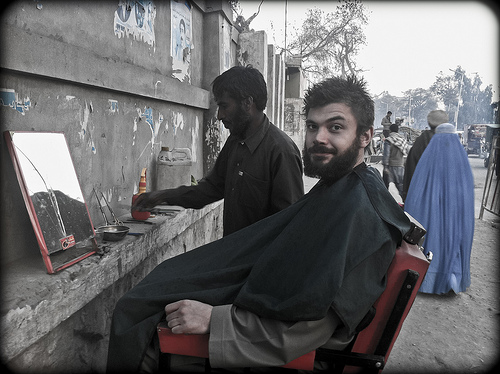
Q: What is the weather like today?
A: It is cloudy.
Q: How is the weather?
A: It is cloudy.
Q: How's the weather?
A: It is cloudy.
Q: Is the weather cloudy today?
A: Yes, it is cloudy.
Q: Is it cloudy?
A: Yes, it is cloudy.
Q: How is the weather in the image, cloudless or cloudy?
A: It is cloudy.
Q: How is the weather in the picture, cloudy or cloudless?
A: It is cloudy.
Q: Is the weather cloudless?
A: No, it is cloudy.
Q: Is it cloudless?
A: No, it is cloudy.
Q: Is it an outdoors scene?
A: Yes, it is outdoors.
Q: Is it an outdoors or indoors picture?
A: It is outdoors.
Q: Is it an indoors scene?
A: No, it is outdoors.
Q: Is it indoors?
A: No, it is outdoors.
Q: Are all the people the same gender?
A: No, they are both male and female.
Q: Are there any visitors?
A: No, there are no visitors.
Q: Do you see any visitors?
A: No, there are no visitors.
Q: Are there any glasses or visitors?
A: No, there are no visitors or glasses.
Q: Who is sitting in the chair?
A: The man is sitting in the chair.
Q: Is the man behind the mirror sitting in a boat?
A: No, the man is sitting in the chair.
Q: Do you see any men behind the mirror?
A: Yes, there is a man behind the mirror.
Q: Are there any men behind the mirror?
A: Yes, there is a man behind the mirror.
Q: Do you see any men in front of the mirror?
A: No, the man is behind the mirror.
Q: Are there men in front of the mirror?
A: No, the man is behind the mirror.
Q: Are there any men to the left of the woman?
A: Yes, there is a man to the left of the woman.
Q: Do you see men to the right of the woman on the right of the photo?
A: No, the man is to the left of the woman.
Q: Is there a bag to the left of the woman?
A: No, there is a man to the left of the woman.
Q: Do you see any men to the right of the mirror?
A: Yes, there is a man to the right of the mirror.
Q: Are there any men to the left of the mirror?
A: No, the man is to the right of the mirror.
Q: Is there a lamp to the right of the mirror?
A: No, there is a man to the right of the mirror.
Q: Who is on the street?
A: The man is on the street.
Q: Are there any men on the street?
A: Yes, there is a man on the street.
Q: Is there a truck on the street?
A: No, there is a man on the street.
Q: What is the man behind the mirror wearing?
A: The man is wearing a shirt.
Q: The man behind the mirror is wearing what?
A: The man is wearing a shirt.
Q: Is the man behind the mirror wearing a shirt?
A: Yes, the man is wearing a shirt.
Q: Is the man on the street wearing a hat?
A: No, the man is wearing a shirt.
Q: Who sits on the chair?
A: The man sits on the chair.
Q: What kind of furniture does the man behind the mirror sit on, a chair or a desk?
A: The man sits on a chair.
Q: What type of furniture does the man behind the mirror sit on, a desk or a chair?
A: The man sits on a chair.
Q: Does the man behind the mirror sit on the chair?
A: Yes, the man sits on the chair.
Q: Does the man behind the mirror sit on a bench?
A: No, the man sits on the chair.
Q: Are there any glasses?
A: No, there are no glasses.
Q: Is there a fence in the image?
A: No, there are no fences.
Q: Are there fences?
A: No, there are no fences.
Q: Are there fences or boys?
A: No, there are no fences or boys.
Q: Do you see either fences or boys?
A: No, there are no fences or boys.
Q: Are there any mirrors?
A: Yes, there is a mirror.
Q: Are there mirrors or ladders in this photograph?
A: Yes, there is a mirror.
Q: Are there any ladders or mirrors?
A: Yes, there is a mirror.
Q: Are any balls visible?
A: No, there are no balls.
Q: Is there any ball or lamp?
A: No, there are no balls or lamps.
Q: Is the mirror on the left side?
A: Yes, the mirror is on the left of the image.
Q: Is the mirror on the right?
A: No, the mirror is on the left of the image.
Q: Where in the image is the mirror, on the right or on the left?
A: The mirror is on the left of the image.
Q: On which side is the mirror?
A: The mirror is on the left of the image.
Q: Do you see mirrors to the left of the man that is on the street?
A: Yes, there is a mirror to the left of the man.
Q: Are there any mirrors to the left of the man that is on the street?
A: Yes, there is a mirror to the left of the man.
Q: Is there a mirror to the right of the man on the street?
A: No, the mirror is to the left of the man.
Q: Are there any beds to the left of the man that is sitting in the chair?
A: No, there is a mirror to the left of the man.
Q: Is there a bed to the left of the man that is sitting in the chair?
A: No, there is a mirror to the left of the man.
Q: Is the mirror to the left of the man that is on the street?
A: Yes, the mirror is to the left of the man.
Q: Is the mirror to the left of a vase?
A: No, the mirror is to the left of the man.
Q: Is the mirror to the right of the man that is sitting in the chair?
A: No, the mirror is to the left of the man.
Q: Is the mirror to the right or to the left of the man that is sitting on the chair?
A: The mirror is to the left of the man.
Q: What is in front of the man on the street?
A: The mirror is in front of the man.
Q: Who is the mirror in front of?
A: The mirror is in front of the man.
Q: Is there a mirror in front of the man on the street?
A: Yes, there is a mirror in front of the man.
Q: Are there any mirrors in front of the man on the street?
A: Yes, there is a mirror in front of the man.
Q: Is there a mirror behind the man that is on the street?
A: No, the mirror is in front of the man.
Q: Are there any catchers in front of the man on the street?
A: No, there is a mirror in front of the man.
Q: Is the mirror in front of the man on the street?
A: Yes, the mirror is in front of the man.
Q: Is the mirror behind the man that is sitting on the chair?
A: No, the mirror is in front of the man.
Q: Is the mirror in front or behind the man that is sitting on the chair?
A: The mirror is in front of the man.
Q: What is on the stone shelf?
A: The mirror is on the shelf.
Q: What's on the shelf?
A: The mirror is on the shelf.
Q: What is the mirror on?
A: The mirror is on the shelf.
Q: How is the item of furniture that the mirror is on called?
A: The piece of furniture is a shelf.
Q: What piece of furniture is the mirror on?
A: The mirror is on the shelf.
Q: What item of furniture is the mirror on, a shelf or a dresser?
A: The mirror is on a shelf.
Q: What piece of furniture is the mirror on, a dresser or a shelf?
A: The mirror is on a shelf.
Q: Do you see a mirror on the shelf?
A: Yes, there is a mirror on the shelf.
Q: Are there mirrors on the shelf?
A: Yes, there is a mirror on the shelf.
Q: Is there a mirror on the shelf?
A: Yes, there is a mirror on the shelf.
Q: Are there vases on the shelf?
A: No, there is a mirror on the shelf.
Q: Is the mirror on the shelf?
A: Yes, the mirror is on the shelf.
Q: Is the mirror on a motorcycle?
A: No, the mirror is on the shelf.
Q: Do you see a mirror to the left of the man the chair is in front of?
A: Yes, there is a mirror to the left of the man.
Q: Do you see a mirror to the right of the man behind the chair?
A: No, the mirror is to the left of the man.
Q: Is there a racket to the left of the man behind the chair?
A: No, there is a mirror to the left of the man.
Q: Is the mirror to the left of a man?
A: Yes, the mirror is to the left of a man.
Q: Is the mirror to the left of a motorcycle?
A: No, the mirror is to the left of a man.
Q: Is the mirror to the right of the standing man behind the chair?
A: No, the mirror is to the left of the man.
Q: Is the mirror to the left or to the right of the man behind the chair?
A: The mirror is to the left of the man.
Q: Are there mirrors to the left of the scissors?
A: Yes, there is a mirror to the left of the scissors.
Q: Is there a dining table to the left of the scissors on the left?
A: No, there is a mirror to the left of the scissors.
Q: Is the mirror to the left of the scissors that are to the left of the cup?
A: Yes, the mirror is to the left of the scissors.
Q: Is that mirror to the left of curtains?
A: No, the mirror is to the left of the scissors.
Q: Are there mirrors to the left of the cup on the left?
A: Yes, there is a mirror to the left of the cup.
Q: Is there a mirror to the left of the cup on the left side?
A: Yes, there is a mirror to the left of the cup.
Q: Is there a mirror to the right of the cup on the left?
A: No, the mirror is to the left of the cup.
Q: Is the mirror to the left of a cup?
A: Yes, the mirror is to the left of a cup.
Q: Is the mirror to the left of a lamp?
A: No, the mirror is to the left of a cup.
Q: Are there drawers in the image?
A: No, there are no drawers.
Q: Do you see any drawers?
A: No, there are no drawers.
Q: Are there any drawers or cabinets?
A: No, there are no drawers or cabinets.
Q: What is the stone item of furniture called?
A: The piece of furniture is a shelf.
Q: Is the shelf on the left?
A: Yes, the shelf is on the left of the image.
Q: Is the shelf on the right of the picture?
A: No, the shelf is on the left of the image.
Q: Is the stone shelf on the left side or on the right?
A: The shelf is on the left of the image.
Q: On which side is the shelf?
A: The shelf is on the left of the image.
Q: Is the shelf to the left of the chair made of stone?
A: Yes, the shelf is made of stone.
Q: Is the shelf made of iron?
A: No, the shelf is made of stone.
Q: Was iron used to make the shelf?
A: No, the shelf is made of stone.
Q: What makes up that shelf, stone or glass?
A: The shelf is made of stone.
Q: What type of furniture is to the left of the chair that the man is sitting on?
A: The piece of furniture is a shelf.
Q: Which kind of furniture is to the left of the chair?
A: The piece of furniture is a shelf.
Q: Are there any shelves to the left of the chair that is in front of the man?
A: Yes, there is a shelf to the left of the chair.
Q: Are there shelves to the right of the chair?
A: No, the shelf is to the left of the chair.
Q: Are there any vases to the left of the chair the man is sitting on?
A: No, there is a shelf to the left of the chair.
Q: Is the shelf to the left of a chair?
A: Yes, the shelf is to the left of a chair.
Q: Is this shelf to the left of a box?
A: No, the shelf is to the left of a chair.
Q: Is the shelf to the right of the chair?
A: No, the shelf is to the left of the chair.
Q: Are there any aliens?
A: No, there are no aliens.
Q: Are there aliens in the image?
A: No, there are no aliens.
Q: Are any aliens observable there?
A: No, there are no aliens.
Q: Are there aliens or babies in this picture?
A: No, there are no aliens or babies.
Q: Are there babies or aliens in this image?
A: No, there are no aliens or babies.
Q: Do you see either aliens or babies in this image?
A: No, there are no aliens or babies.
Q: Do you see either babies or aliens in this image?
A: No, there are no aliens or babies.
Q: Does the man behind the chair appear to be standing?
A: Yes, the man is standing.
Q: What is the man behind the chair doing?
A: The man is standing.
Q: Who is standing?
A: The man is standing.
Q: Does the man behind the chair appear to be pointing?
A: No, the man is standing.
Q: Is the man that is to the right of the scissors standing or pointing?
A: The man is standing.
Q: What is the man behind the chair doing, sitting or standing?
A: The man is standing.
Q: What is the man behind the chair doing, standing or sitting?
A: The man is standing.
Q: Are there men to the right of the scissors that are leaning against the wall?
A: Yes, there is a man to the right of the scissors.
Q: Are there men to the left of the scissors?
A: No, the man is to the right of the scissors.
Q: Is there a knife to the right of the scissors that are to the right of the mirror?
A: No, there is a man to the right of the scissors.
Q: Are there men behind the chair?
A: Yes, there is a man behind the chair.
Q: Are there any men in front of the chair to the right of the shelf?
A: No, the man is behind the chair.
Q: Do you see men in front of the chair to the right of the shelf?
A: No, the man is behind the chair.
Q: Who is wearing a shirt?
A: The man is wearing a shirt.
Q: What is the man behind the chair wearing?
A: The man is wearing a shirt.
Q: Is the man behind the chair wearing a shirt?
A: Yes, the man is wearing a shirt.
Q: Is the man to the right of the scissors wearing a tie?
A: No, the man is wearing a shirt.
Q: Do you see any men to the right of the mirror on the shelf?
A: Yes, there is a man to the right of the mirror.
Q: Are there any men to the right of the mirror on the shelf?
A: Yes, there is a man to the right of the mirror.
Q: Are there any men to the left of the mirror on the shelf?
A: No, the man is to the right of the mirror.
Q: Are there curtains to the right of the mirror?
A: No, there is a man to the right of the mirror.